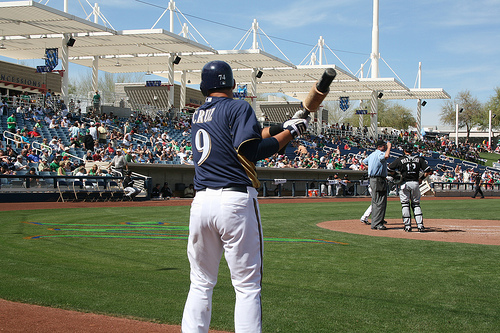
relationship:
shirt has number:
[185, 99, 261, 191] [188, 121, 214, 168]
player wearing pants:
[173, 52, 311, 331] [177, 188, 268, 330]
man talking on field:
[363, 135, 401, 235] [6, 193, 497, 327]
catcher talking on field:
[387, 143, 432, 232] [6, 193, 497, 327]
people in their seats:
[2, 96, 137, 179] [5, 90, 133, 207]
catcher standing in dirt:
[387, 143, 432, 232] [9, 196, 497, 327]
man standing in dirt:
[363, 135, 401, 235] [9, 196, 497, 327]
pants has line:
[171, 189, 272, 330] [245, 190, 268, 330]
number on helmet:
[210, 68, 236, 90] [198, 56, 241, 97]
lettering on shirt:
[189, 105, 220, 134] [188, 86, 263, 199]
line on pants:
[245, 190, 268, 330] [177, 188, 268, 330]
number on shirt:
[189, 125, 210, 167] [177, 90, 265, 195]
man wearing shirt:
[363, 135, 401, 235] [362, 146, 393, 187]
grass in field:
[7, 189, 496, 324] [6, 193, 497, 327]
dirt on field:
[2, 298, 209, 330] [6, 193, 497, 327]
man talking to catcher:
[363, 135, 401, 235] [385, 135, 432, 241]